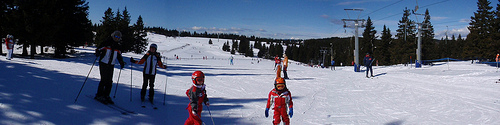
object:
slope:
[0, 39, 158, 125]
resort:
[2, 0, 500, 125]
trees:
[88, 3, 121, 55]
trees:
[455, 0, 500, 66]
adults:
[90, 29, 130, 108]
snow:
[0, 31, 498, 124]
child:
[180, 70, 214, 124]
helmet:
[187, 70, 209, 86]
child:
[258, 77, 297, 125]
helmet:
[267, 76, 292, 86]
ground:
[0, 34, 499, 124]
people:
[356, 51, 378, 78]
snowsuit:
[176, 86, 215, 125]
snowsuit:
[264, 90, 298, 124]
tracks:
[305, 105, 347, 125]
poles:
[157, 62, 177, 108]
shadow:
[1, 61, 302, 125]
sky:
[81, 1, 499, 40]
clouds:
[329, 18, 474, 39]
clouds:
[182, 24, 311, 38]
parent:
[126, 38, 175, 104]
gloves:
[259, 107, 273, 118]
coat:
[133, 52, 167, 75]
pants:
[265, 105, 296, 125]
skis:
[79, 94, 138, 118]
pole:
[407, 23, 428, 68]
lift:
[231, 0, 498, 34]